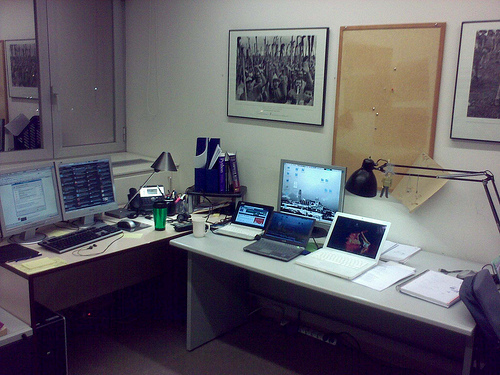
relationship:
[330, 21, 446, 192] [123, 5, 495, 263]
board hanging on wall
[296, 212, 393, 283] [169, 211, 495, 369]
laptop on desk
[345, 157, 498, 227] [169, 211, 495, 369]
lamp on desk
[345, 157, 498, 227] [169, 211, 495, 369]
lamp extended over desk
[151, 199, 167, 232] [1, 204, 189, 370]
cup on desk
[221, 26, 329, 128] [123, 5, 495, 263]
art on wall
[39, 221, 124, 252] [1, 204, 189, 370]
keyboard on desk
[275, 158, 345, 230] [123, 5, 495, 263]
computer monitor near wall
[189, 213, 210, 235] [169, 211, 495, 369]
mug on desk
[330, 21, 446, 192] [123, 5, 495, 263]
board on wall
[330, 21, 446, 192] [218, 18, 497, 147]
board between images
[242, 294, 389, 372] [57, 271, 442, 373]
cords on ground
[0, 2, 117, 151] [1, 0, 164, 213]
mirror on wall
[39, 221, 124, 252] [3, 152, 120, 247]
keyboard for computer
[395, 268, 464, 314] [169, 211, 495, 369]
notepad sitting on desk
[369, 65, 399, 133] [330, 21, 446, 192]
pins pushed into board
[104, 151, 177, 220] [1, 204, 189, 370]
lamp on desk